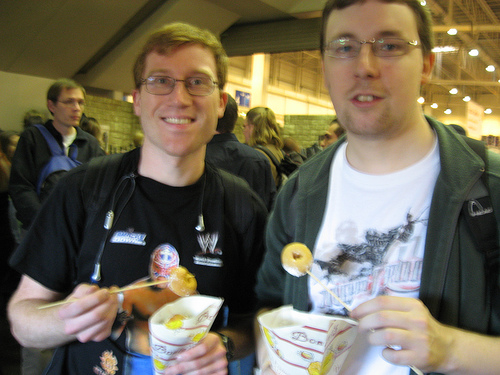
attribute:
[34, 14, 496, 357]
scene — inside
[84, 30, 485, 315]
people — posing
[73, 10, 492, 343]
boys — eating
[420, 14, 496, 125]
lights — distant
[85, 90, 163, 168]
wall — gray, stone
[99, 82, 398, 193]
people — walking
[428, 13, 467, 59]
light — white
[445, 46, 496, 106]
light — white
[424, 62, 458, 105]
light — white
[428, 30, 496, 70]
light — white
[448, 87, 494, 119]
light — white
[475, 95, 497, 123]
light — white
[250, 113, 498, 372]
jacket — green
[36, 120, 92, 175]
backpack — blue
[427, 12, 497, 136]
lights — hanging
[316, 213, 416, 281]
design — wrestler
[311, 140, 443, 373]
shirt — white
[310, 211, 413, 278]
design — wrestler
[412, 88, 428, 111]
light — white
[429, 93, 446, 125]
light — white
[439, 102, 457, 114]
light — white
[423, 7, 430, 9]
light — white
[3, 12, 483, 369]
men — posing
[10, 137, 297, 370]
shirt — black, wrestling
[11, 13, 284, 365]
man — on the left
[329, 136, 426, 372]
shirt — white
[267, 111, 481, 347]
jacket — green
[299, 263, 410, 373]
stick — thin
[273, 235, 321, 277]
donut — tiny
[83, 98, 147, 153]
wall — gray, brick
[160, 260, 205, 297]
donut — tiny, yellow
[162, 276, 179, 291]
sugar — powdered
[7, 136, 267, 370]
t-shirt — black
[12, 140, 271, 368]
shirt — man's